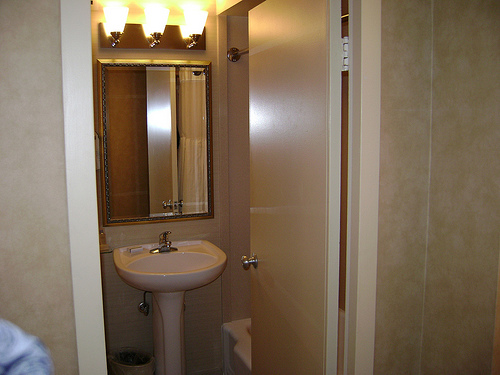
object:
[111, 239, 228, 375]
sink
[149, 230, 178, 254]
faucet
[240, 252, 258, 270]
door knob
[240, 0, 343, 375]
door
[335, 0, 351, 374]
gap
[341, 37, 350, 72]
hinge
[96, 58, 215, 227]
mirror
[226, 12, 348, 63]
shower rod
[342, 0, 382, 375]
frame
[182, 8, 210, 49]
light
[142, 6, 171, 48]
light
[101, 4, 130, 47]
light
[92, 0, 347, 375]
bathroom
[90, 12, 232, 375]
wall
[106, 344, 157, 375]
wastebasket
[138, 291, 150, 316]
plumbing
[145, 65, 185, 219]
door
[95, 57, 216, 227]
frame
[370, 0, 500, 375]
wallpaper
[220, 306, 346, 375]
bathtub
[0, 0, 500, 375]
scene